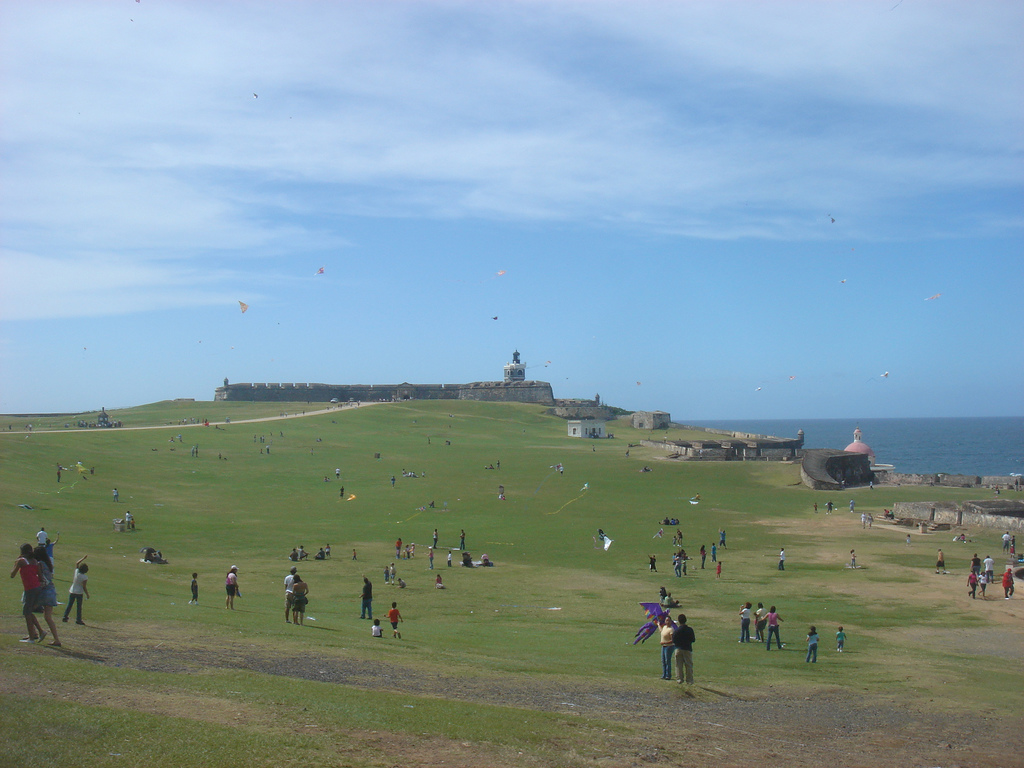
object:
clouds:
[0, 0, 1015, 241]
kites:
[922, 291, 943, 304]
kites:
[490, 314, 500, 322]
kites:
[495, 268, 507, 276]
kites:
[879, 369, 894, 379]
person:
[736, 601, 752, 644]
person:
[357, 572, 375, 619]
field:
[0, 395, 1024, 765]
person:
[671, 614, 697, 687]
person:
[836, 626, 848, 652]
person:
[759, 606, 786, 651]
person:
[383, 601, 405, 638]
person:
[61, 553, 94, 628]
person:
[805, 625, 822, 664]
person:
[224, 564, 243, 610]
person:
[283, 566, 299, 624]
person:
[187, 572, 200, 606]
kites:
[312, 267, 326, 277]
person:
[753, 601, 770, 642]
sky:
[0, 8, 1018, 426]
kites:
[237, 300, 250, 314]